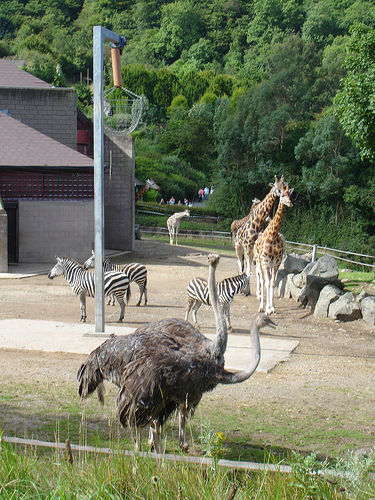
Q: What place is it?
A: It is a zoo.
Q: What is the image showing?
A: It is showing a zoo.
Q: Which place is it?
A: It is a zoo.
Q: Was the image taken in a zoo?
A: Yes, it was taken in a zoo.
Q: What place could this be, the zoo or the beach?
A: It is the zoo.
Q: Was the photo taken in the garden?
A: No, the picture was taken in the zoo.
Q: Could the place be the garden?
A: No, it is the zoo.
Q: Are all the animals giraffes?
A: No, there are both giraffes and zebras.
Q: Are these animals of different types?
A: Yes, they are giraffes and zebras.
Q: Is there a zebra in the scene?
A: Yes, there is a zebra.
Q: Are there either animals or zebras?
A: Yes, there is a zebra.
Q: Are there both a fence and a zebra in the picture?
A: Yes, there are both a zebra and a fence.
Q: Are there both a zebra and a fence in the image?
A: Yes, there are both a zebra and a fence.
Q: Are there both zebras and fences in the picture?
A: Yes, there are both a zebra and a fence.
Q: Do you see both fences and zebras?
A: Yes, there are both a zebra and a fence.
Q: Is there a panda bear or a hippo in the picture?
A: No, there are no hippos or panda bears.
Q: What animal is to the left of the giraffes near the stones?
A: The animal is a zebra.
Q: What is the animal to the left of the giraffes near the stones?
A: The animal is a zebra.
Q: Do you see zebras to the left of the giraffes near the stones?
A: Yes, there is a zebra to the left of the giraffes.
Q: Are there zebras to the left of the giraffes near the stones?
A: Yes, there is a zebra to the left of the giraffes.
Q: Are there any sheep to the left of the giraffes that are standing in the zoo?
A: No, there is a zebra to the left of the giraffes.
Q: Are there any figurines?
A: No, there are no figurines.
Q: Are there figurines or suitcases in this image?
A: No, there are no figurines or suitcases.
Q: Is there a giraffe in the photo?
A: Yes, there are giraffes.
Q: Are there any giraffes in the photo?
A: Yes, there are giraffes.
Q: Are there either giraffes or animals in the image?
A: Yes, there are giraffes.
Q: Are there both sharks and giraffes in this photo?
A: No, there are giraffes but no sharks.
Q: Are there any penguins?
A: No, there are no penguins.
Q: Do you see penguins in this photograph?
A: No, there are no penguins.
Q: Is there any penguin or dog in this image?
A: No, there are no penguins or dogs.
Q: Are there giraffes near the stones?
A: Yes, there are giraffes near the stones.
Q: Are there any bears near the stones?
A: No, there are giraffes near the stones.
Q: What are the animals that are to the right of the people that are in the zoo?
A: The animals are giraffes.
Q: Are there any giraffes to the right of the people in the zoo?
A: Yes, there are giraffes to the right of the people.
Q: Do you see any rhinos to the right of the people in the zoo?
A: No, there are giraffes to the right of the people.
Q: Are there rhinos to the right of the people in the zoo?
A: No, there are giraffes to the right of the people.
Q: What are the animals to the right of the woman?
A: The animals are giraffes.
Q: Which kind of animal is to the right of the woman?
A: The animals are giraffes.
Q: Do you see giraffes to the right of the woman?
A: Yes, there are giraffes to the right of the woman.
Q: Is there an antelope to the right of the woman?
A: No, there are giraffes to the right of the woman.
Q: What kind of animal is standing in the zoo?
A: The animals are giraffes.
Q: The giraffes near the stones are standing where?
A: The giraffes are standing in the zoo.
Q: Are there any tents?
A: No, there are no tents.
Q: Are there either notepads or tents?
A: No, there are no tents or notepads.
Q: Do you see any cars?
A: No, there are no cars.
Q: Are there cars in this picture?
A: No, there are no cars.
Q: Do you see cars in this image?
A: No, there are no cars.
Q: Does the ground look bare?
A: Yes, the ground is bare.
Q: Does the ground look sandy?
A: No, the ground is bare.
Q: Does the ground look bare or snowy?
A: The ground is bare.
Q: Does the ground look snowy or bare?
A: The ground is bare.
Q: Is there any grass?
A: Yes, there is grass.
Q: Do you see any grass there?
A: Yes, there is grass.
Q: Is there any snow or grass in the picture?
A: Yes, there is grass.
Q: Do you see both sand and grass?
A: No, there is grass but no sand.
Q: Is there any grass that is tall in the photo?
A: Yes, there is tall grass.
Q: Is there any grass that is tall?
A: Yes, there is grass that is tall.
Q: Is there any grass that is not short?
A: Yes, there is tall grass.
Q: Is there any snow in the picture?
A: No, there is no snow.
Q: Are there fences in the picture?
A: Yes, there is a fence.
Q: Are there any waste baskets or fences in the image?
A: Yes, there is a fence.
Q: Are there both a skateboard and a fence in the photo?
A: No, there is a fence but no skateboards.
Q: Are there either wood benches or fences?
A: Yes, there is a wood fence.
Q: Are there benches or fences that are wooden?
A: Yes, the fence is wooden.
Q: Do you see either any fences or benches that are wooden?
A: Yes, the fence is wooden.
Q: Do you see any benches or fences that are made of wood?
A: Yes, the fence is made of wood.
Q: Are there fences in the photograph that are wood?
A: Yes, there is a wood fence.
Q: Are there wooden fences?
A: Yes, there is a wood fence.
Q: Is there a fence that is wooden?
A: Yes, there is a fence that is wooden.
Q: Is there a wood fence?
A: Yes, there is a fence that is made of wood.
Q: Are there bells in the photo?
A: No, there are no bells.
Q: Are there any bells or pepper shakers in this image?
A: No, there are no bells or pepper shakers.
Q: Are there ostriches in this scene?
A: Yes, there are ostriches.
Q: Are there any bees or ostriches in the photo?
A: Yes, there are ostriches.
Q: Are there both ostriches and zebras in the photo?
A: Yes, there are both ostriches and a zebra.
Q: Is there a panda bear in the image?
A: No, there are no panda bears.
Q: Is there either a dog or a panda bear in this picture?
A: No, there are no panda bears or dogs.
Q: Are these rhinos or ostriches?
A: These are ostriches.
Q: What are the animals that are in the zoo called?
A: The animals are ostriches.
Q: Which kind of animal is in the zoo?
A: The animals are ostriches.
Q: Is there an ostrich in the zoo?
A: Yes, there are ostriches in the zoo.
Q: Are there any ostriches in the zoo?
A: Yes, there are ostriches in the zoo.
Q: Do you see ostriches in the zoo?
A: Yes, there are ostriches in the zoo.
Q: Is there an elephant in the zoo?
A: No, there are ostriches in the zoo.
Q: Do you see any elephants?
A: No, there are no elephants.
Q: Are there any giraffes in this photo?
A: Yes, there is a giraffe.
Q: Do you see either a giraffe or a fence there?
A: Yes, there is a giraffe.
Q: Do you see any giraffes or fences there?
A: Yes, there is a giraffe.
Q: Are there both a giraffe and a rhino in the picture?
A: No, there is a giraffe but no rhinos.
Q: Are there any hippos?
A: No, there are no hippos.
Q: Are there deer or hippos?
A: No, there are no hippos or deer.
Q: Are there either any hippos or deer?
A: No, there are no hippos or deer.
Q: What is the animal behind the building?
A: The animal is a giraffe.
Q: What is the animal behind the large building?
A: The animal is a giraffe.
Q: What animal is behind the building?
A: The animal is a giraffe.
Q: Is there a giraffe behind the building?
A: Yes, there is a giraffe behind the building.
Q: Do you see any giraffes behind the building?
A: Yes, there is a giraffe behind the building.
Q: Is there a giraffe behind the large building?
A: Yes, there is a giraffe behind the building.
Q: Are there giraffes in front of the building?
A: No, the giraffe is behind the building.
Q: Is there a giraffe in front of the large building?
A: No, the giraffe is behind the building.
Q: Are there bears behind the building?
A: No, there is a giraffe behind the building.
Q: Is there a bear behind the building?
A: No, there is a giraffe behind the building.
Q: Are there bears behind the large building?
A: No, there is a giraffe behind the building.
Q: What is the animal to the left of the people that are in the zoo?
A: The animal is a giraffe.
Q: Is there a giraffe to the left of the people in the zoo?
A: Yes, there is a giraffe to the left of the people.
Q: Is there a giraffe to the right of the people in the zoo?
A: No, the giraffe is to the left of the people.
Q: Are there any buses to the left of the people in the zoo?
A: No, there is a giraffe to the left of the people.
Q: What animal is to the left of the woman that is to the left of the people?
A: The animal is a giraffe.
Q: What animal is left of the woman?
A: The animal is a giraffe.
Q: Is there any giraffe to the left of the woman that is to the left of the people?
A: Yes, there is a giraffe to the left of the woman.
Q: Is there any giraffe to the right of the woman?
A: No, the giraffe is to the left of the woman.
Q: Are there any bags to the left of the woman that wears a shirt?
A: No, there is a giraffe to the left of the woman.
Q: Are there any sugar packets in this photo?
A: No, there are no sugar packets.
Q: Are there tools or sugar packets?
A: No, there are no sugar packets or tools.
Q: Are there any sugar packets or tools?
A: No, there are no sugar packets or tools.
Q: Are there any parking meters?
A: No, there are no parking meters.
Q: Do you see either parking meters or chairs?
A: No, there are no parking meters or chairs.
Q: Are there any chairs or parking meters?
A: No, there are no parking meters or chairs.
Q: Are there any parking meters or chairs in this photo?
A: No, there are no parking meters or chairs.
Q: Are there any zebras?
A: Yes, there are zebras.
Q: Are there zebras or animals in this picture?
A: Yes, there are zebras.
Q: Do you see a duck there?
A: No, there are no ducks.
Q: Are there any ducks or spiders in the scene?
A: No, there are no ducks or spiders.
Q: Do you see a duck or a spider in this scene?
A: No, there are no ducks or spiders.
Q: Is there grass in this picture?
A: Yes, there is grass.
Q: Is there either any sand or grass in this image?
A: Yes, there is grass.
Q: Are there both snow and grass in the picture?
A: No, there is grass but no snow.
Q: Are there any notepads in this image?
A: No, there are no notepads.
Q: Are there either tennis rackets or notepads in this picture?
A: No, there are no notepads or tennis rackets.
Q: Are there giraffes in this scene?
A: Yes, there are giraffes.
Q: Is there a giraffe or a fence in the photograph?
A: Yes, there are giraffes.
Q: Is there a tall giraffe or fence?
A: Yes, there are tall giraffes.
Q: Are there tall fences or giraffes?
A: Yes, there are tall giraffes.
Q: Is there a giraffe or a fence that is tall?
A: Yes, the giraffes are tall.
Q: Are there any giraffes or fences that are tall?
A: Yes, the giraffes are tall.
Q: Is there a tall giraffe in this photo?
A: Yes, there are tall giraffes.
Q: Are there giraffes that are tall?
A: Yes, there are giraffes that are tall.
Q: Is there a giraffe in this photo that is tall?
A: Yes, there are giraffes that are tall.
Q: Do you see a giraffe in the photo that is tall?
A: Yes, there are giraffes that are tall.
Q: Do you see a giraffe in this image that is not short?
A: Yes, there are tall giraffes.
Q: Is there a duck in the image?
A: No, there are no ducks.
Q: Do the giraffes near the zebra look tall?
A: Yes, the giraffes are tall.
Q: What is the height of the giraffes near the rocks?
A: The giraffes are tall.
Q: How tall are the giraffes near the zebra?
A: The giraffes are tall.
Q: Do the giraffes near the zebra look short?
A: No, the giraffes are tall.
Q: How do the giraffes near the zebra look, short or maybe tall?
A: The giraffes are tall.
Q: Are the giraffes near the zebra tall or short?
A: The giraffes are tall.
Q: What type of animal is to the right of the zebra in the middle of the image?
A: The animals are giraffes.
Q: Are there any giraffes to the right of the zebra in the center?
A: Yes, there are giraffes to the right of the zebra.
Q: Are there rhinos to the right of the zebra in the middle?
A: No, there are giraffes to the right of the zebra.